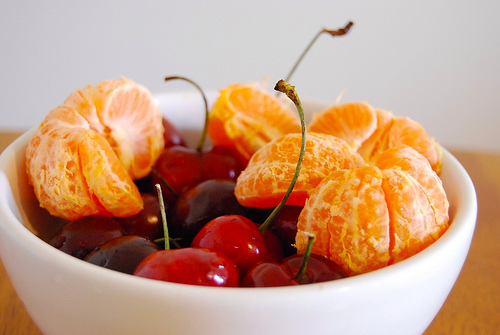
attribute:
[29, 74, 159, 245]
orange — white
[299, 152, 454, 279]
orange — white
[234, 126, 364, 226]
orange — white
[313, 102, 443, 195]
orange — white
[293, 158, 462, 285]
orange — white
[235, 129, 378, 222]
orange — white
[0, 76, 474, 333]
bowl — white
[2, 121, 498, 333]
table — wood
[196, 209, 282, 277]
cherry — vibrant red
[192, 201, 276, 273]
cherry — vibrant red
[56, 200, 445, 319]
bowl — white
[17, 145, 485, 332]
bowl — white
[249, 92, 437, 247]
oranges — peeled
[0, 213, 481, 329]
bowl — white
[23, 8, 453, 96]
walls — white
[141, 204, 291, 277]
cherries — red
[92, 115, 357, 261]
fruit — tasty, fresh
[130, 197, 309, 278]
cherries — red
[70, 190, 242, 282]
cherries — dark red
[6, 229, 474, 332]
bowl — white, ceramic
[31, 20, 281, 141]
wall — white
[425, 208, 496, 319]
table — wooden